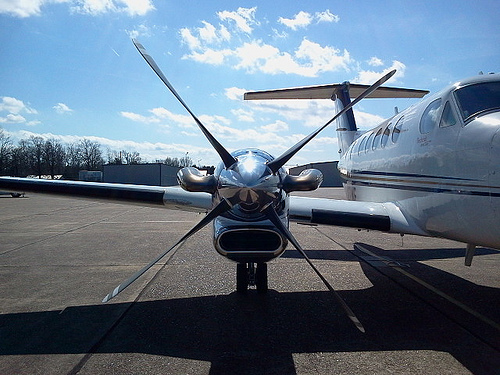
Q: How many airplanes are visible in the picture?
A: One.